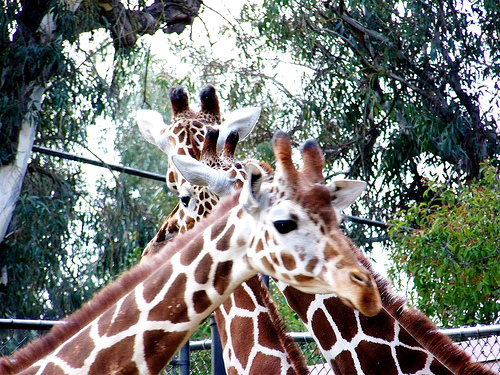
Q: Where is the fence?
A: Behind the giraffes.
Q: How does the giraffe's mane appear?
A: Fuzzy.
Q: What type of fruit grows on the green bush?
A: Red berries.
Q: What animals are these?
A: Giraffes.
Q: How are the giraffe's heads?
A: Horny.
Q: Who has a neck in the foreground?
A: Giraffe.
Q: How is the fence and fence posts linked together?
A: Chains.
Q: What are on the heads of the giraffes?
A: Horns.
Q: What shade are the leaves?
A: Green.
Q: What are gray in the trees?
A: Branches.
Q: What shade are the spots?
A: Brown.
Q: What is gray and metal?
A: Fence.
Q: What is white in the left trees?
A: Bark.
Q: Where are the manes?
A: On the necks.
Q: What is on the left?
A: Tree trunk.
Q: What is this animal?
A: Giraffes.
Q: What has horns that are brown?
A: Giraffes.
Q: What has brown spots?
A: Giraffes.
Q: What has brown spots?
A: Giraffes.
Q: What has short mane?
A: The giraffe.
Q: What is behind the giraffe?
A: A fence.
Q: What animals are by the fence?
A: Giraffes.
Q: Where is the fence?
A: By the animals.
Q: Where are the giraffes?
A: By the fence.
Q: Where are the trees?
A: Behind the fence.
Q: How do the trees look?
A: Healthy.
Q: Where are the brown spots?
A: On the giraffes.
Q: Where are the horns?
A: On the heads of the giraffes.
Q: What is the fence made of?
A: Metal.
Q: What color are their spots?
A: Brown.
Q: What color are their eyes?
A: Black.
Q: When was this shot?
A: Daytime.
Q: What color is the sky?
A: Blue.